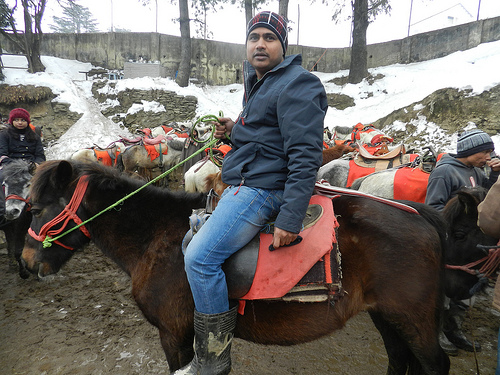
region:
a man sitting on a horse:
[14, 27, 339, 337]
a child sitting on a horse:
[0, 92, 60, 217]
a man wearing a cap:
[233, 7, 290, 83]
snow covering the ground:
[21, 54, 216, 121]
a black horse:
[426, 176, 491, 306]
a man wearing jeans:
[188, 178, 283, 339]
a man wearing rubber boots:
[192, 278, 234, 374]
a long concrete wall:
[16, 12, 493, 76]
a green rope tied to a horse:
[18, 102, 247, 264]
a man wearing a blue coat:
[198, 37, 319, 219]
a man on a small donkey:
[19, 12, 451, 372]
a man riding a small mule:
[22, 10, 446, 373]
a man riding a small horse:
[20, 10, 448, 373]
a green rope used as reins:
[42, 134, 223, 246]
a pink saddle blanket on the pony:
[242, 187, 332, 301]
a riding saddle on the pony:
[183, 184, 320, 304]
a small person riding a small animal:
[0, 108, 44, 243]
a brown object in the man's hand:
[269, 232, 304, 250]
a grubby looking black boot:
[176, 309, 233, 373]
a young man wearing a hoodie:
[426, 126, 497, 352]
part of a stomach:
[310, 298, 342, 315]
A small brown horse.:
[19, 156, 451, 373]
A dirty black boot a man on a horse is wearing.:
[168, 301, 238, 373]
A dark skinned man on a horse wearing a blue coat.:
[173, 10, 330, 373]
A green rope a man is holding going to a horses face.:
[41, 110, 226, 249]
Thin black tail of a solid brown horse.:
[403, 200, 452, 328]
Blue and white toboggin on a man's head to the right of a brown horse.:
[453, 117, 495, 155]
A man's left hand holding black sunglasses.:
[272, 224, 297, 248]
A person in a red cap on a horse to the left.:
[1, 106, 47, 170]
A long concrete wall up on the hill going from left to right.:
[0, 15, 499, 81]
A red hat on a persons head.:
[6, 106, 32, 124]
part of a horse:
[383, 213, 439, 290]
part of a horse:
[286, 293, 303, 312]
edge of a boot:
[193, 298, 228, 328]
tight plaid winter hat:
[242, 9, 289, 58]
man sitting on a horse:
[166, 8, 329, 374]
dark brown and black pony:
[17, 157, 452, 374]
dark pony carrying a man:
[20, 9, 454, 374]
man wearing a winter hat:
[423, 122, 498, 354]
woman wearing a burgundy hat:
[0, 104, 49, 274]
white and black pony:
[0, 157, 48, 282]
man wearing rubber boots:
[167, 9, 324, 373]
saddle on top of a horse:
[184, 170, 344, 310]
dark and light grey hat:
[455, 115, 495, 157]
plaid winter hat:
[245, 8, 287, 60]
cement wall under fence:
[0, 0, 498, 85]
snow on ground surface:
[0, 40, 498, 154]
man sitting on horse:
[22, 10, 451, 372]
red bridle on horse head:
[20, 157, 93, 275]